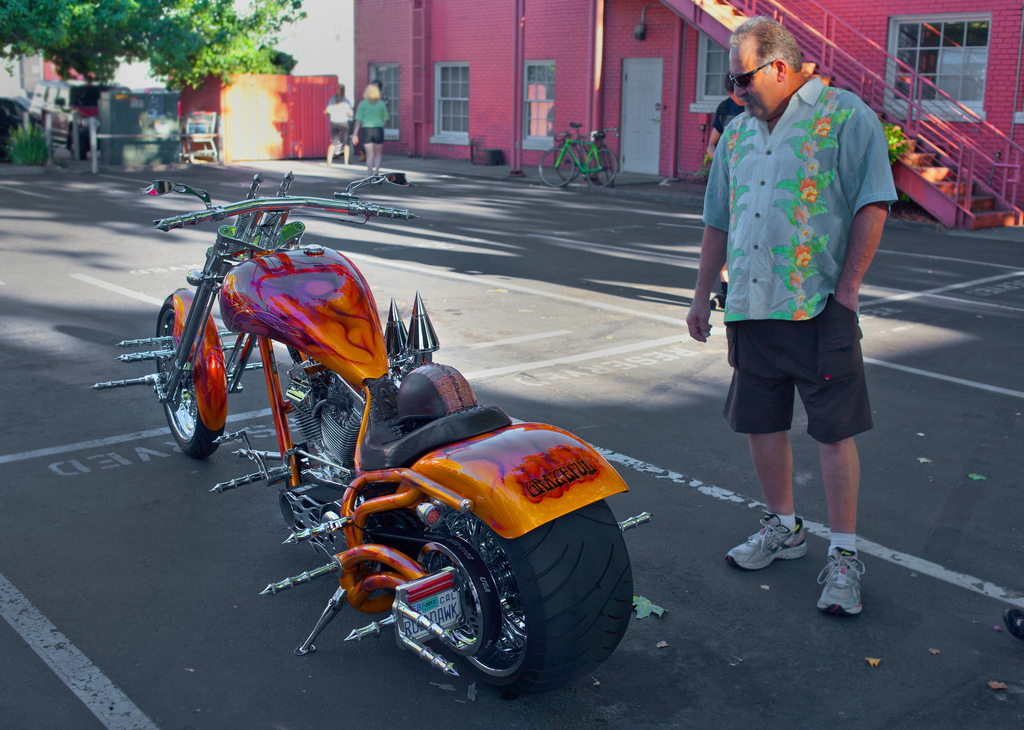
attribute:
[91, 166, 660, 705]
motorcycle — custom painted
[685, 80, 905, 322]
shirt — patterned 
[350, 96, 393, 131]
shirt — green 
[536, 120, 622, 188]
bicycle — green 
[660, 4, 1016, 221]
staircase — red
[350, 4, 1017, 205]
building — metal 